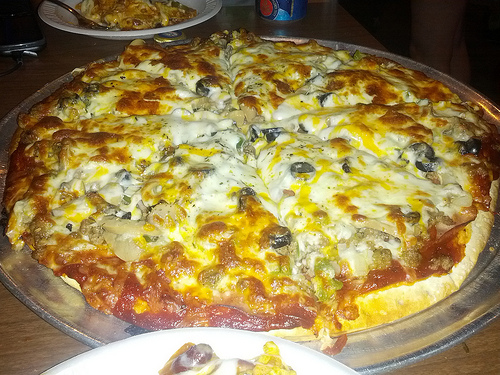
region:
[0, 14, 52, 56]
phone laying on the table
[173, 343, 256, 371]
slice of pizza on a plate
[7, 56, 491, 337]
silver tray with food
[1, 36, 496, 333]
big pizza on top of a silver tray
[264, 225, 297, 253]
a black olive topping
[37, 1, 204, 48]
dinner plate with food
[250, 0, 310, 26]
blue beverage can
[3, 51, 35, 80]
phone charging wire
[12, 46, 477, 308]
pizza with cheese, polives, and onions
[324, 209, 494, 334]
pizza crust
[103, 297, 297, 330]
the pizza has sauce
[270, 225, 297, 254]
the pizza has olives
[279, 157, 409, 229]
the pizza has melted cheese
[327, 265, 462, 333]
the pizza has crust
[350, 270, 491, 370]
the pizza is on a tray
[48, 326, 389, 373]
the plate is white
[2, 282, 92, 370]
the tray of pizza is on a table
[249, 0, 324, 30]
a can is on the table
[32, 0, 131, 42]
a fork sits on a plate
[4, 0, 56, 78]
a cell phone is charging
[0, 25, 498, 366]
the pizza is on a silver tray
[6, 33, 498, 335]
the pizza is very cheesy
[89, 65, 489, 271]
the pizza has black olives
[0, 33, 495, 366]
the pizza is deep dish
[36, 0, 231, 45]
the plate is white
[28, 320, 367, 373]
the plate has pizza on it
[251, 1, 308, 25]
the can is blue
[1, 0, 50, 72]
the phone is black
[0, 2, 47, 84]
the phone is plugged into a charger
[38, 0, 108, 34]
the white bowl has a fork in it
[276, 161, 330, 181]
Olives on the pizza.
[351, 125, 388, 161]
Cheddar cheese on the pizza.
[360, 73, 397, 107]
The pizza has burnt cheese.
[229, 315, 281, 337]
Sauce on the crust.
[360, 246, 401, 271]
Sausage on the pizza.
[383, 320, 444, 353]
Pizza is on a pie pan.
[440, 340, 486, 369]
The table is wooden.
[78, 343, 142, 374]
The plate is white.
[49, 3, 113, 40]
Fork in a bowl.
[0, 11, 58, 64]
Cell phone on a table.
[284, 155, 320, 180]
Sliced black olive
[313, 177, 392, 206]
Melted orange and white cheeses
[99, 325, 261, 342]
Part of a white plate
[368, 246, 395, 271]
Chunk of cooked sausage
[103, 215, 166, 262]
A large beige mushroom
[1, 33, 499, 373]
Large round metal pan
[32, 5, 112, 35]
A silver fork laying on a plate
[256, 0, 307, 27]
Bottom part of a soda can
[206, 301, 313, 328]
Red tomato sauce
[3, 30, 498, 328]
What looks like a delicious pizza